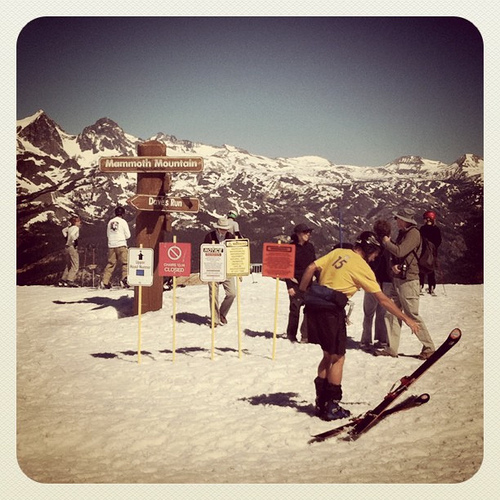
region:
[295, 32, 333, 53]
white clouds in blue sky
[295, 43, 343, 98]
white clouds in blue sky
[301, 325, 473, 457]
black snow ski's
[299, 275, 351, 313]
black fanny pack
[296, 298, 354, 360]
black shorts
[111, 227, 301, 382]
five signs on poles in snow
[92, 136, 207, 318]
two brown direction signs on brown pole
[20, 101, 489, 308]
snow covered mountains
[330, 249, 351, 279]
number on back of yellow t-shirt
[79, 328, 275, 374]
shadow of signs on ground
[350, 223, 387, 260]
black helmet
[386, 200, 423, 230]
green hat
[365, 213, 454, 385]
man is setting ski down on the ground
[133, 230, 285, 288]
signs posted with warnings and cautions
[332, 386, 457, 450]
snow skis are laying in the snow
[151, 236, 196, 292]
the sign is red and square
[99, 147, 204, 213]
wooden sign on a large post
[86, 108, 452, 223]
snow capped mountains in the background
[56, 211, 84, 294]
woman is standing on edge of hill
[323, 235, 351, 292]
man is wearing a yellow t-shirt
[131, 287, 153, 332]
sign is on a wooden post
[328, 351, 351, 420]
a man's leg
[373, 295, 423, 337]
a man's hand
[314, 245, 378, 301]
a yellow t-shirt worn by a man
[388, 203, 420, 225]
a hat on a man's head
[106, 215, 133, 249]
a white t-shirt worn by a man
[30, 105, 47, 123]
the top of a rock on a mountain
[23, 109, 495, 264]
a rock mountain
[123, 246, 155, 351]
a white banner on a short pole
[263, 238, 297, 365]
a red banner on a pole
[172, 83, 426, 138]
the sky over the rocky mountain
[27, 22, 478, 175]
bright blue sky over mountains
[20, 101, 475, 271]
snow-covered peaks of rocky mountains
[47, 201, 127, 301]
people of top of snow looking at mountains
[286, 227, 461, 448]
skier with number leaning over her skis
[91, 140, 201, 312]
brown destination signs on brown column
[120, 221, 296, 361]
series of signs on poles in a row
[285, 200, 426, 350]
people talking to each other behind skier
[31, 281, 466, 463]
footprints and shadows across snow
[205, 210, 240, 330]
person in gray hat walking toward signs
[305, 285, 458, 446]
person extending hand toward slanted ski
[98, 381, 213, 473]
Large patch of snow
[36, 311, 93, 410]
Large patch of snow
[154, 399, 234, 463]
Large patch of snow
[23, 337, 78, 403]
Large patch of snow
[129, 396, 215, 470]
Large patch of snow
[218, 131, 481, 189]
Mountains in the distance